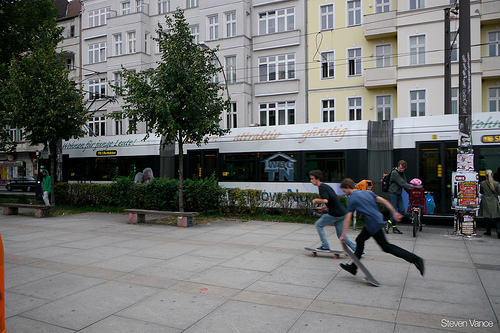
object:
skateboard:
[340, 241, 380, 287]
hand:
[339, 236, 346, 244]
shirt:
[317, 182, 347, 217]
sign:
[458, 181, 477, 206]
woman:
[479, 169, 499, 239]